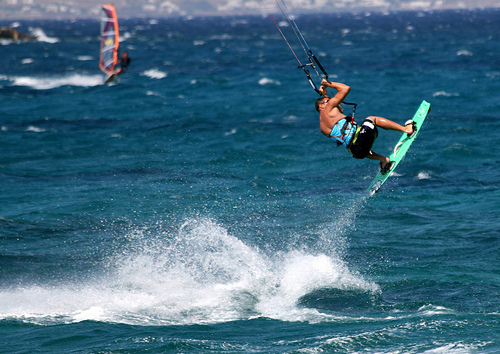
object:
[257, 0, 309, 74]
kite string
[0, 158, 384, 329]
splashing water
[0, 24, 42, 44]
mountain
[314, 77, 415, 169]
guy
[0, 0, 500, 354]
ripples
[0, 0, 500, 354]
water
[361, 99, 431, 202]
surfboard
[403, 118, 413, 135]
feet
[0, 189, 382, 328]
waves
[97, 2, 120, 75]
waterski sail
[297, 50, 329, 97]
handles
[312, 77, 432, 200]
surfing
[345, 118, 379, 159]
suit